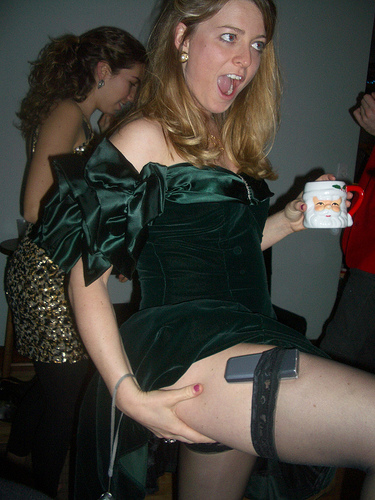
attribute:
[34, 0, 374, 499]
woman — white, horny, happy, blonde, pretty, beautiful, drunk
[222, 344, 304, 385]
telephone — cellular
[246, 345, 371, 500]
stocking — green, thigh-high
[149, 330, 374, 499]
leg — voluptuous, white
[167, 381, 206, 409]
thumb — manicured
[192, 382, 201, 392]
nail — pink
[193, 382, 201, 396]
polish — pink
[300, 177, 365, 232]
mug — white, shaped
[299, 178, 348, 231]
santa claus — sculpted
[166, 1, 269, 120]
face — happy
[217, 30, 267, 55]
eyes — beautiful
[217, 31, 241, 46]
eye — beautiful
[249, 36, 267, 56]
eye — beautiful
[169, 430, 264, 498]
leg — voluptuous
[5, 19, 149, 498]
girl — beautiful, smiling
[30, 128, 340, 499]
dress — green, nice, special, shiny, velvet, off shoulder, satin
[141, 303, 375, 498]
right leg — raised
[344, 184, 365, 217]
handle — red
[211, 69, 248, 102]
mouth — open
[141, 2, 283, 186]
hair — free, long, blonde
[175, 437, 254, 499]
stocking — thigh-high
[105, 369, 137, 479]
strap — grey, camera strap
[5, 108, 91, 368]
dress — sequined, gold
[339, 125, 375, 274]
sweatshirt — red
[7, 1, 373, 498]
scene — indoors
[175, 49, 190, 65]
earring — gold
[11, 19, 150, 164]
hair — curly, blonde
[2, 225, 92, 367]
skirt — lame, gold